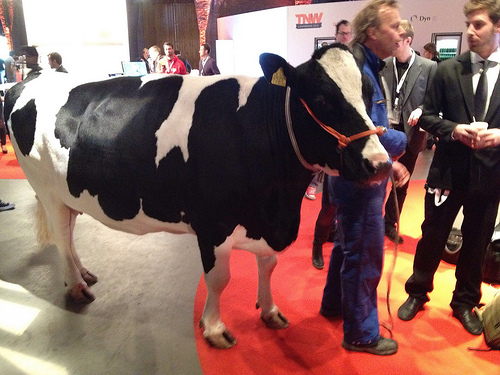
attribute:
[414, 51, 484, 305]
suit — black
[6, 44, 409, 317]
cow — black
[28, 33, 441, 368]
large cow — black and white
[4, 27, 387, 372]
cow is white — black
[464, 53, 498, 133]
neck tie — black